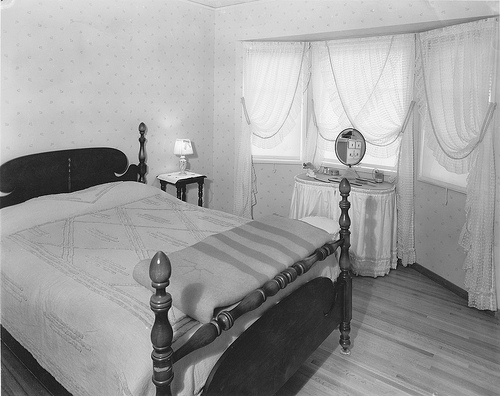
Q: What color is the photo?
A: Black and white.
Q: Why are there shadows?
A: From lighting.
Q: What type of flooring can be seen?
A: Wood.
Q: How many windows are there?
A: 3.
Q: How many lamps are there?
A: 1.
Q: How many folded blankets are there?
A: 1.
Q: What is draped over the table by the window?
A: Tablecloth.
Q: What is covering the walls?
A: Wallpaper.